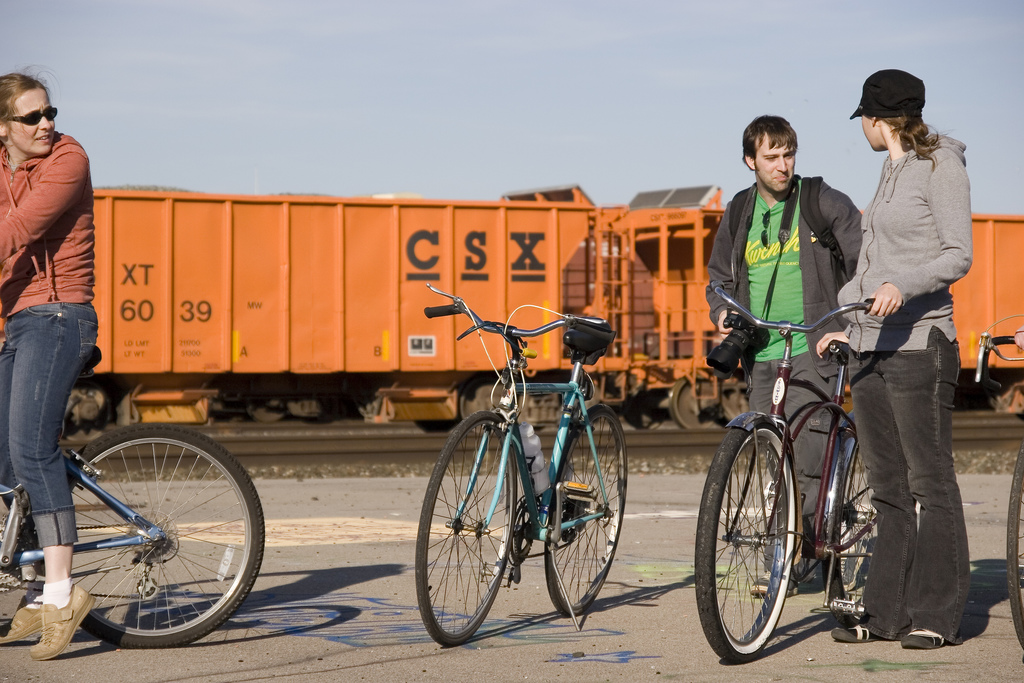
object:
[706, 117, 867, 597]
person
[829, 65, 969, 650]
person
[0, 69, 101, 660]
person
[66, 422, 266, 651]
tire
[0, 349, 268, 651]
bike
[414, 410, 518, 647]
tire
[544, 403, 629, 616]
tire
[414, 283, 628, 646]
bike